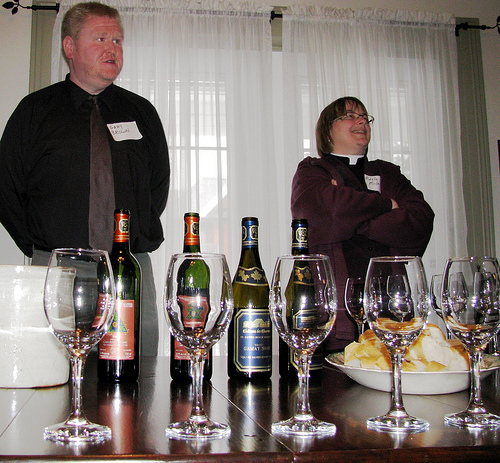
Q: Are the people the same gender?
A: No, they are both male and female.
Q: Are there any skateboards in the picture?
A: No, there are no skateboards.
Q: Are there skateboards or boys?
A: No, there are no skateboards or boys.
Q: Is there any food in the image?
A: Yes, there is food.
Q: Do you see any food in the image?
A: Yes, there is food.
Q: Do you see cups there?
A: No, there are no cups.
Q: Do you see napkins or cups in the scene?
A: No, there are no cups or napkins.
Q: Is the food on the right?
A: Yes, the food is on the right of the image.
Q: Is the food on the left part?
A: No, the food is on the right of the image.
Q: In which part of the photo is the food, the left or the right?
A: The food is on the right of the image.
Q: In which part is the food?
A: The food is on the right of the image.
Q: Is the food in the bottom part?
A: Yes, the food is in the bottom of the image.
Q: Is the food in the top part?
A: No, the food is in the bottom of the image.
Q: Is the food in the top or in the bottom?
A: The food is in the bottom of the image.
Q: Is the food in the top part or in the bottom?
A: The food is in the bottom of the image.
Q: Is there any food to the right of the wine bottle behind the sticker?
A: Yes, there is food to the right of the wine bottle.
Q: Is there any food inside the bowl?
A: Yes, there is food inside the bowl.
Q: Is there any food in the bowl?
A: Yes, there is food in the bowl.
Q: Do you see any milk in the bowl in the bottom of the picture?
A: No, there is food in the bowl.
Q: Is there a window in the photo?
A: Yes, there is a window.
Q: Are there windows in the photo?
A: Yes, there is a window.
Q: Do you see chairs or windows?
A: Yes, there is a window.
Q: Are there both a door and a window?
A: No, there is a window but no doors.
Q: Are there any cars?
A: No, there are no cars.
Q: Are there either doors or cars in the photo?
A: No, there are no cars or doors.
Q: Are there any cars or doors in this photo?
A: No, there are no cars or doors.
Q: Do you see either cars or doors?
A: No, there are no cars or doors.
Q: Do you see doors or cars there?
A: No, there are no cars or doors.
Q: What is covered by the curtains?
A: The window is covered by the curtains.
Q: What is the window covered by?
A: The window is covered by the curtains.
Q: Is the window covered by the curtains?
A: Yes, the window is covered by the curtains.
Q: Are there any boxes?
A: No, there are no boxes.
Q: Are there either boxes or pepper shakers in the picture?
A: No, there are no boxes or pepper shakers.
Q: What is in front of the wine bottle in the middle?
A: The sticker is in front of the wine bottle.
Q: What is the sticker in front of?
A: The sticker is in front of the wine bottle.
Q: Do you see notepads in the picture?
A: No, there are no notepads.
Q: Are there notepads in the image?
A: No, there are no notepads.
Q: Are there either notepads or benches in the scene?
A: No, there are no notepads or benches.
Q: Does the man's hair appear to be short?
A: Yes, the hair is short.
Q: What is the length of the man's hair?
A: The hair is short.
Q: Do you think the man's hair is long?
A: No, the hair is short.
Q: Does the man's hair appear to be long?
A: No, the hair is short.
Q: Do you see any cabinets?
A: No, there are no cabinets.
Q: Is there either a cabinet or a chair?
A: No, there are no cabinets or chairs.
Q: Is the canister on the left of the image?
A: Yes, the canister is on the left of the image.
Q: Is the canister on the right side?
A: No, the canister is on the left of the image.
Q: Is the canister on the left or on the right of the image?
A: The canister is on the left of the image.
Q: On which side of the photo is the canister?
A: The canister is on the left of the image.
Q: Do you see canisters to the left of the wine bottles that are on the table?
A: Yes, there is a canister to the left of the wine bottles.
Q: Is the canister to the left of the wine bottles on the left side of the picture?
A: Yes, the canister is to the left of the wine bottles.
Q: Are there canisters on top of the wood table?
A: Yes, there is a canister on top of the table.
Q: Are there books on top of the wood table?
A: No, there is a canister on top of the table.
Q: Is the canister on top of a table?
A: Yes, the canister is on top of a table.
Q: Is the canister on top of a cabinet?
A: No, the canister is on top of a table.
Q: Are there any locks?
A: No, there are no locks.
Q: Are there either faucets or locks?
A: No, there are no locks or faucets.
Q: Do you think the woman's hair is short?
A: Yes, the hair is short.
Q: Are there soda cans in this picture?
A: No, there are no soda cans.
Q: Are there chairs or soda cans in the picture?
A: No, there are no soda cans or chairs.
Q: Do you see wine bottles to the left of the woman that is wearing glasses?
A: Yes, there is a wine bottle to the left of the woman.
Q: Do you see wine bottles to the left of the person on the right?
A: Yes, there is a wine bottle to the left of the woman.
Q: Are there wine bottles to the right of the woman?
A: No, the wine bottle is to the left of the woman.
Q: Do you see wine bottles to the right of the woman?
A: No, the wine bottle is to the left of the woman.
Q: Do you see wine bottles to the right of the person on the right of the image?
A: No, the wine bottle is to the left of the woman.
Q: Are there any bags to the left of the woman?
A: No, there is a wine bottle to the left of the woman.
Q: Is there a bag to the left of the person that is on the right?
A: No, there is a wine bottle to the left of the woman.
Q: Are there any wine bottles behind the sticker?
A: Yes, there is a wine bottle behind the sticker.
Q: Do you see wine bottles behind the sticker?
A: Yes, there is a wine bottle behind the sticker.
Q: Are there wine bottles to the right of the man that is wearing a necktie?
A: Yes, there is a wine bottle to the right of the man.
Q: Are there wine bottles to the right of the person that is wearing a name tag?
A: Yes, there is a wine bottle to the right of the man.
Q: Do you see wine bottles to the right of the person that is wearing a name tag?
A: Yes, there is a wine bottle to the right of the man.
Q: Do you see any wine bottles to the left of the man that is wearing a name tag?
A: No, the wine bottle is to the right of the man.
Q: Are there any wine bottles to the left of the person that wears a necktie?
A: No, the wine bottle is to the right of the man.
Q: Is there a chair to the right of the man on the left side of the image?
A: No, there is a wine bottle to the right of the man.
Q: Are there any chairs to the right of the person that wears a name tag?
A: No, there is a wine bottle to the right of the man.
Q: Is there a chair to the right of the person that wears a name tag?
A: No, there is a wine bottle to the right of the man.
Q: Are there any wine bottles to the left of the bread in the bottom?
A: Yes, there is a wine bottle to the left of the bread.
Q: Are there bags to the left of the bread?
A: No, there is a wine bottle to the left of the bread.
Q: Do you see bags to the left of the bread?
A: No, there is a wine bottle to the left of the bread.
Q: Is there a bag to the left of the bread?
A: No, there is a wine bottle to the left of the bread.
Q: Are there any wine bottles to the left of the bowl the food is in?
A: Yes, there is a wine bottle to the left of the bowl.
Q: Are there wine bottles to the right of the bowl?
A: No, the wine bottle is to the left of the bowl.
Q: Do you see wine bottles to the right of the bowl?
A: No, the wine bottle is to the left of the bowl.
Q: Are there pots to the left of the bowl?
A: No, there is a wine bottle to the left of the bowl.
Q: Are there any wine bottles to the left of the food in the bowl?
A: Yes, there is a wine bottle to the left of the food.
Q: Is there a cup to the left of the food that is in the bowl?
A: No, there is a wine bottle to the left of the food.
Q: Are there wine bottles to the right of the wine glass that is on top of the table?
A: Yes, there is a wine bottle to the right of the wineglass.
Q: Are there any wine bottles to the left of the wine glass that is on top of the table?
A: No, the wine bottle is to the right of the wine glass.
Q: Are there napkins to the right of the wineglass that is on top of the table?
A: No, there is a wine bottle to the right of the wine glass.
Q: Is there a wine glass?
A: Yes, there is a wine glass.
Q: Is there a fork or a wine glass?
A: Yes, there is a wine glass.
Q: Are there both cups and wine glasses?
A: No, there is a wine glass but no cups.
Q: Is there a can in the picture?
A: No, there are no cans.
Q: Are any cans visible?
A: No, there are no cans.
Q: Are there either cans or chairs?
A: No, there are no cans or chairs.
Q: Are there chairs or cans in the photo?
A: No, there are no cans or chairs.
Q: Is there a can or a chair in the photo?
A: No, there are no cans or chairs.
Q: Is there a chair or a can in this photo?
A: No, there are no cans or chairs.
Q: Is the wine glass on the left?
A: Yes, the wine glass is on the left of the image.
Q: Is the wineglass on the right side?
A: No, the wineglass is on the left of the image.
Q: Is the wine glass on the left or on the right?
A: The wine glass is on the left of the image.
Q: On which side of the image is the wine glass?
A: The wine glass is on the left of the image.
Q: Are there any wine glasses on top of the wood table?
A: Yes, there is a wine glass on top of the table.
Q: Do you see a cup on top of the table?
A: No, there is a wine glass on top of the table.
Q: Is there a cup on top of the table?
A: No, there is a wine glass on top of the table.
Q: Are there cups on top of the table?
A: No, there is a wine glass on top of the table.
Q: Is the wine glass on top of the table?
A: Yes, the wine glass is on top of the table.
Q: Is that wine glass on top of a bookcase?
A: No, the wine glass is on top of the table.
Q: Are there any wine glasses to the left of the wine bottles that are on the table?
A: Yes, there is a wine glass to the left of the wine bottles.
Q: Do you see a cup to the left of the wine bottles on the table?
A: No, there is a wine glass to the left of the wine bottles.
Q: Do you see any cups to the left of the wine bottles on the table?
A: No, there is a wine glass to the left of the wine bottles.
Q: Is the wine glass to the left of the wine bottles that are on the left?
A: Yes, the wine glass is to the left of the wine bottles.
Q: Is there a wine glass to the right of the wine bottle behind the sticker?
A: No, the wine glass is to the left of the wine bottle.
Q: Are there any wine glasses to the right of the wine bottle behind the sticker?
A: No, the wine glass is to the left of the wine bottle.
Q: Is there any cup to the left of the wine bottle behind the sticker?
A: No, there is a wine glass to the left of the wine bottle.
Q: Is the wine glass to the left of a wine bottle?
A: Yes, the wine glass is to the left of a wine bottle.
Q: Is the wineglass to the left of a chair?
A: No, the wineglass is to the left of a wine bottle.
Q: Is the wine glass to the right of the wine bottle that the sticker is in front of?
A: No, the wine glass is to the left of the wine bottle.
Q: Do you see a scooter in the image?
A: No, there are no scooters.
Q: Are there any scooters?
A: No, there are no scooters.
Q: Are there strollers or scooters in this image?
A: No, there are no scooters or strollers.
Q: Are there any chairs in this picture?
A: No, there are no chairs.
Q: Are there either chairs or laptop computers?
A: No, there are no chairs or laptop computers.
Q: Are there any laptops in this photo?
A: No, there are no laptops.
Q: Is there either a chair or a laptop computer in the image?
A: No, there are no laptops or chairs.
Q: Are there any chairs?
A: No, there are no chairs.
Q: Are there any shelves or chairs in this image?
A: No, there are no chairs or shelves.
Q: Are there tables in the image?
A: Yes, there is a table.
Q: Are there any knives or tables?
A: Yes, there is a table.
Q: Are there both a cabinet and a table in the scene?
A: No, there is a table but no cabinets.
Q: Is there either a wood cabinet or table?
A: Yes, there is a wood table.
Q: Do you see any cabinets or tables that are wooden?
A: Yes, the table is wooden.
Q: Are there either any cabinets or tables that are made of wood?
A: Yes, the table is made of wood.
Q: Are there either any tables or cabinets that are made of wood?
A: Yes, the table is made of wood.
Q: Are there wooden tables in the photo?
A: Yes, there is a wood table.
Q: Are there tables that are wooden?
A: Yes, there is a table that is wooden.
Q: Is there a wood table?
A: Yes, there is a table that is made of wood.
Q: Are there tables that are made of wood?
A: Yes, there is a table that is made of wood.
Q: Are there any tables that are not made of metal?
A: Yes, there is a table that is made of wood.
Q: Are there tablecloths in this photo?
A: No, there are no tablecloths.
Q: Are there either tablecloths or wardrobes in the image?
A: No, there are no tablecloths or wardrobes.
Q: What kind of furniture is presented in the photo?
A: The furniture is a table.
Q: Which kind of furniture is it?
A: The piece of furniture is a table.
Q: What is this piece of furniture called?
A: This is a table.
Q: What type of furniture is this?
A: This is a table.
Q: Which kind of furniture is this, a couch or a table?
A: This is a table.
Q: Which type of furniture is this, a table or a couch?
A: This is a table.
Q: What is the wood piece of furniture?
A: The piece of furniture is a table.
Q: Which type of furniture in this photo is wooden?
A: The furniture is a table.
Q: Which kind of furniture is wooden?
A: The furniture is a table.